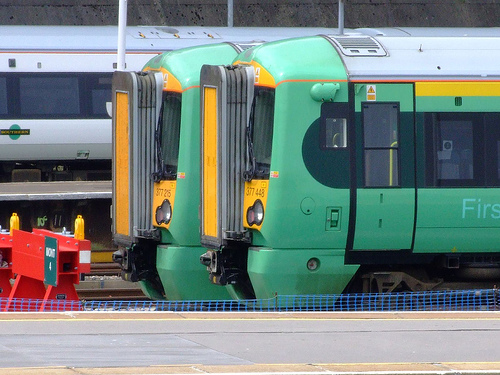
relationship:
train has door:
[108, 32, 500, 311] [349, 78, 423, 268]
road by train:
[13, 308, 499, 366] [108, 32, 500, 311]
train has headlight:
[108, 32, 500, 311] [245, 196, 267, 231]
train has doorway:
[108, 40, 261, 300] [110, 68, 164, 248]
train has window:
[108, 32, 500, 311] [431, 115, 474, 179]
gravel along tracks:
[83, 267, 124, 282] [10, 261, 491, 319]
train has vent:
[108, 32, 500, 311] [326, 30, 382, 58]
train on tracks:
[108, 40, 261, 300] [10, 261, 491, 319]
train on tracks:
[108, 32, 500, 311] [10, 261, 491, 319]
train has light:
[108, 32, 500, 311] [305, 257, 327, 279]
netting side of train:
[5, 293, 500, 318] [108, 32, 500, 311]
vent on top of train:
[326, 30, 382, 58] [108, 32, 500, 311]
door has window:
[349, 78, 423, 268] [365, 102, 400, 144]